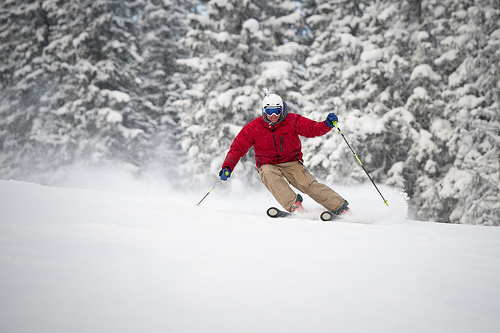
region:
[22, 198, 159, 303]
Snow covered ground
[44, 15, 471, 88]
Row of snow covered pine trees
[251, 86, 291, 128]
Man wearing white helmet and snow goggles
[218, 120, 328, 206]
Man wearing red jacket and tan snow pants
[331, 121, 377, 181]
Black and lime green ski pole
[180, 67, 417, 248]
Man skiing in front of snow covered trees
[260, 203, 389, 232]
Pair of skis on the snow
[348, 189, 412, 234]
Snow flying thru air from skier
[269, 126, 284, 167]
Black zipper in middle of red jacket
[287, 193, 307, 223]
Red boot attached to ski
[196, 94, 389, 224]
Man skiing on snow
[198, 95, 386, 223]
Man holding ski poles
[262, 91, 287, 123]
Man wearing white helmet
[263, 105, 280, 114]
Blue and white googles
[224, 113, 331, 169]
Man wearing red jacket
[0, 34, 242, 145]
Trees covered with snow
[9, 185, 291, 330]
Ground covered with snow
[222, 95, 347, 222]
Man wearing warm clothes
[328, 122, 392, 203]
green and black ski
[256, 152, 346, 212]
Man wearing beige pants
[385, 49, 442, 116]
part of a tree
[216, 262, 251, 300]
part of a snow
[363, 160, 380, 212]
part of a hooker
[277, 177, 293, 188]
part of a trouser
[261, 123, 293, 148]
part of a jacket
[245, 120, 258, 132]
part of a shoulder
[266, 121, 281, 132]
part of a collar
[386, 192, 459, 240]
part of a splash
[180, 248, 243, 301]
part of a snow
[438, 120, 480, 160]
part of a tree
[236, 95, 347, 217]
this is a man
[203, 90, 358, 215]
the man is snow skating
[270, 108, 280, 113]
the goggles are blue in color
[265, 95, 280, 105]
this is a helmet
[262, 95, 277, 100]
the helmet is white in color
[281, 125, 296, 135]
the jacket is red in color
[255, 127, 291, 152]
the jacket is heavy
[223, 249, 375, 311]
the place is full of snow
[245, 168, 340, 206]
the legs are slanted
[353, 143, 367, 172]
this is a stick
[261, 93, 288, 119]
a white helmet on a skier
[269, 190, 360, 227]
two skis on a skier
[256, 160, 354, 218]
brown pants on a skier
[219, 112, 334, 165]
a red coat on a skier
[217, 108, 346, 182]
two blue gloves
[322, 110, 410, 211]
a ski pole lifted in the air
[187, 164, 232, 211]
a ski pole in the snow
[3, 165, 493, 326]
a snowy slope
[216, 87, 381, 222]
a skier on a slope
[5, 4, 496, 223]
a snow covered pine forest behind a skier